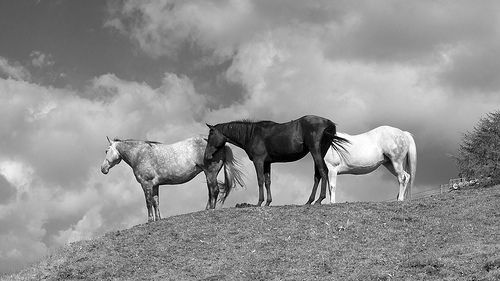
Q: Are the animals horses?
A: Yes, all the animals are horses.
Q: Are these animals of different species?
A: No, all the animals are horses.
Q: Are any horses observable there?
A: Yes, there is a horse.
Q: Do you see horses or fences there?
A: Yes, there is a horse.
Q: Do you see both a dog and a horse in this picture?
A: No, there is a horse but no dogs.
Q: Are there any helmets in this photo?
A: No, there are no helmets.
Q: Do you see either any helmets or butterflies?
A: No, there are no helmets or butterflies.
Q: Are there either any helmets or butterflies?
A: No, there are no helmets or butterflies.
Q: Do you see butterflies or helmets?
A: No, there are no helmets or butterflies.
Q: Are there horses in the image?
A: Yes, there is a horse.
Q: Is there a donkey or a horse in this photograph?
A: Yes, there is a horse.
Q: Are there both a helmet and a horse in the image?
A: No, there is a horse but no helmets.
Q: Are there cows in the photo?
A: No, there are no cows.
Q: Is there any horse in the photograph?
A: Yes, there is a horse.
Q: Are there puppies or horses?
A: Yes, there is a horse.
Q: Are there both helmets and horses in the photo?
A: No, there is a horse but no helmets.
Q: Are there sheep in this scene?
A: No, there are no sheep.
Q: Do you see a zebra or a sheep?
A: No, there are no sheep or zebras.